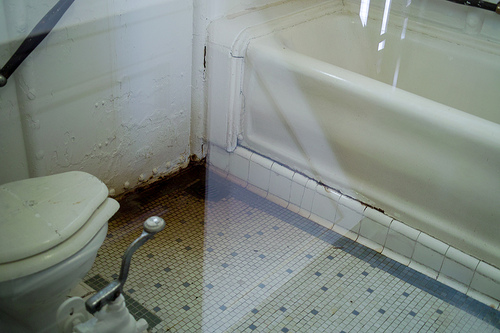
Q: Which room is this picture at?
A: It is at the bathroom.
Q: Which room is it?
A: It is a bathroom.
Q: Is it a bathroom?
A: Yes, it is a bathroom.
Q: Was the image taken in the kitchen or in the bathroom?
A: It was taken at the bathroom.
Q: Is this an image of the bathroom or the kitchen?
A: It is showing the bathroom.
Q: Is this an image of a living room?
A: No, the picture is showing a bathroom.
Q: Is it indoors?
A: Yes, it is indoors.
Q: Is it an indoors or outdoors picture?
A: It is indoors.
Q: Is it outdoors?
A: No, it is indoors.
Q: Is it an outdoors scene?
A: No, it is indoors.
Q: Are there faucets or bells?
A: No, there are no faucets or bells.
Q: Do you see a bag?
A: No, there are no bags.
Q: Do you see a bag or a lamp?
A: No, there are no bags or lamps.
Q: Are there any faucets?
A: No, there are no faucets.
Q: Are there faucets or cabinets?
A: No, there are no faucets or cabinets.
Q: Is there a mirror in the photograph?
A: No, there are no mirrors.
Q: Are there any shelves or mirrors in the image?
A: No, there are no mirrors or shelves.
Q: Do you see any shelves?
A: No, there are no shelves.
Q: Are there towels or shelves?
A: No, there are no shelves or towels.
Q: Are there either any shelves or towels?
A: No, there are no shelves or towels.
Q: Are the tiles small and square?
A: Yes, the tiles are small and square.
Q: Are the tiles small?
A: Yes, the tiles are small.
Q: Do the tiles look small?
A: Yes, the tiles are small.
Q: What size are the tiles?
A: The tiles are small.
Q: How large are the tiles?
A: The tiles are small.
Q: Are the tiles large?
A: No, the tiles are small.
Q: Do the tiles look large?
A: No, the tiles are small.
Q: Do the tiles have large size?
A: No, the tiles are small.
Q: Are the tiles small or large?
A: The tiles are small.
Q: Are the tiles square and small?
A: Yes, the tiles are square and small.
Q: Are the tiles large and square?
A: No, the tiles are square but small.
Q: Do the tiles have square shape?
A: Yes, the tiles are square.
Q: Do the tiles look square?
A: Yes, the tiles are square.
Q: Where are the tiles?
A: The tiles are on the floor.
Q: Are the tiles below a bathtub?
A: Yes, the tiles are below a bathtub.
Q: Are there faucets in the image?
A: No, there are no faucets.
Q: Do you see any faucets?
A: No, there are no faucets.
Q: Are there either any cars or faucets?
A: No, there are no faucets or cars.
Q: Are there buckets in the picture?
A: No, there are no buckets.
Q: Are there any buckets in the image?
A: No, there are no buckets.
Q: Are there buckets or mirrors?
A: No, there are no buckets or mirrors.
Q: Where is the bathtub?
A: The bathtub is in the bathroom.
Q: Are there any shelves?
A: No, there are no shelves.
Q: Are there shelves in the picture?
A: No, there are no shelves.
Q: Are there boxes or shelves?
A: No, there are no shelves or boxes.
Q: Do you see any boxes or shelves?
A: No, there are no shelves or boxes.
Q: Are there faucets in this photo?
A: No, there are no faucets.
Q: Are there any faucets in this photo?
A: No, there are no faucets.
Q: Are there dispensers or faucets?
A: No, there are no faucets or dispensers.